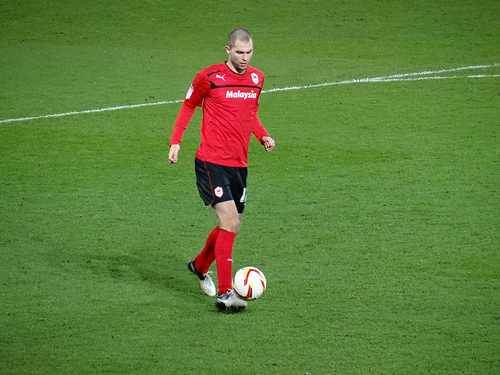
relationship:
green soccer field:
[341, 20, 423, 150] [307, 74, 403, 208]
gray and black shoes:
[188, 261, 239, 321] [186, 253, 266, 319]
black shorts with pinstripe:
[198, 159, 258, 191] [199, 159, 246, 209]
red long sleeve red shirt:
[182, 93, 269, 123] [168, 61, 270, 168]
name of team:
[166, 75, 283, 147] [183, 83, 261, 111]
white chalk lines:
[234, 263, 273, 307] [202, 46, 264, 124]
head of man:
[218, 32, 258, 64] [168, 28, 273, 311]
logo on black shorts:
[195, 183, 283, 222] [195, 157, 248, 213]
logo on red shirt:
[195, 183, 283, 222] [168, 61, 270, 168]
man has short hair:
[168, 28, 273, 311] [218, 32, 258, 64]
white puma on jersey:
[219, 82, 262, 107] [213, 55, 274, 135]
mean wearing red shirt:
[193, 15, 275, 155] [171, 89, 285, 174]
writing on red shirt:
[183, 83, 261, 111] [168, 61, 270, 168]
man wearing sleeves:
[168, 28, 273, 311] [167, 66, 222, 147]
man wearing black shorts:
[168, 28, 273, 311] [195, 157, 248, 213]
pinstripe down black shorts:
[203, 160, 215, 206] [195, 157, 248, 213]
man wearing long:
[168, 28, 273, 311] [194, 225, 236, 297]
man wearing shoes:
[168, 28, 273, 311] [188, 261, 239, 321]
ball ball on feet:
[232, 267, 266, 300] [179, 263, 254, 310]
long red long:
[199, 216, 245, 270] [194, 225, 236, 297]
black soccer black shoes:
[180, 266, 211, 297] [188, 259, 248, 311]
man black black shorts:
[183, 23, 277, 239] [195, 157, 248, 213]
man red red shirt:
[183, 23, 277, 239] [168, 61, 270, 168]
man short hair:
[183, 23, 277, 239] [215, 14, 258, 69]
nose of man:
[235, 54, 248, 62] [168, 28, 273, 311]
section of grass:
[316, 80, 419, 162] [310, 7, 407, 108]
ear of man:
[221, 45, 237, 58] [168, 28, 273, 311]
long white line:
[199, 216, 245, 270] [292, 62, 435, 103]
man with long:
[168, 28, 273, 311] [194, 225, 236, 297]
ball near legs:
[235, 264, 262, 292] [196, 197, 240, 289]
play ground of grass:
[342, 9, 457, 95] [310, 7, 407, 108]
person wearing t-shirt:
[183, 23, 277, 239] [166, 75, 283, 147]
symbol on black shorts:
[189, 174, 243, 224] [195, 157, 248, 213]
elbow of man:
[162, 86, 198, 112] [168, 28, 273, 311]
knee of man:
[209, 191, 245, 238] [168, 28, 273, 311]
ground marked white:
[24, 36, 189, 155] [234, 263, 273, 307]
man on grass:
[168, 28, 273, 311] [310, 7, 407, 108]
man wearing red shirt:
[168, 28, 273, 311] [168, 61, 270, 168]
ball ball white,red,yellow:
[232, 267, 266, 300] [243, 251, 264, 298]